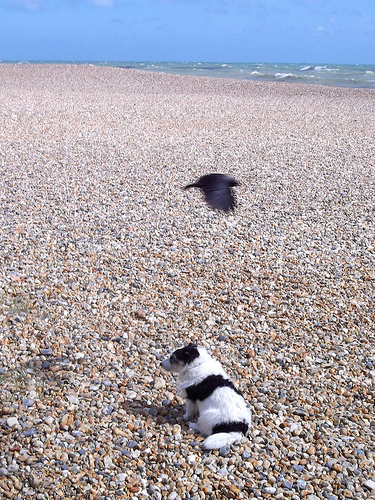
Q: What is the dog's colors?
A: Black and white.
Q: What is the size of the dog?
A: Small.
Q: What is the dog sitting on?
A: Rocks.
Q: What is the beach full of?
A: Pebbles.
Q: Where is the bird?
A: Over the dog.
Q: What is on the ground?
A: Pebbles.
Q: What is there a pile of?
A: Rocks.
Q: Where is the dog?
A: On the beach.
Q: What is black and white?
A: The dog.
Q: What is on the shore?
A: Rocks.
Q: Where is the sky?
A: Over the ocean.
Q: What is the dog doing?
A: Sitting.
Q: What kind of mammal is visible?
A: Dog.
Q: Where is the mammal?
A: On the rocks.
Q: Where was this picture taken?
A: A beach.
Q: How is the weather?
A: Sunny.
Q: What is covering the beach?
A: Rocks.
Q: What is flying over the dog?
A: A bird.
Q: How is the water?
A: Choppy.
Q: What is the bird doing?
A: Flying.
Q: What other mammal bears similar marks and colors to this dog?
A: Skunk.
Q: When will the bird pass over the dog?
A: Now.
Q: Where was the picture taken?
A: Beach.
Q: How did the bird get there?
A: Flew.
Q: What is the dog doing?
A: Sitting.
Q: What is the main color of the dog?
A: White.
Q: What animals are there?
A: Dog and bird.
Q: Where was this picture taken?
A: The beach.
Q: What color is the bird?
A: Black.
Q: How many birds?
A: One.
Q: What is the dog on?
A: A beach of pebbles.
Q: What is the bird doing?
A: Flying.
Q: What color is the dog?
A: Black and white.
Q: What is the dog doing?
A: Sitting.